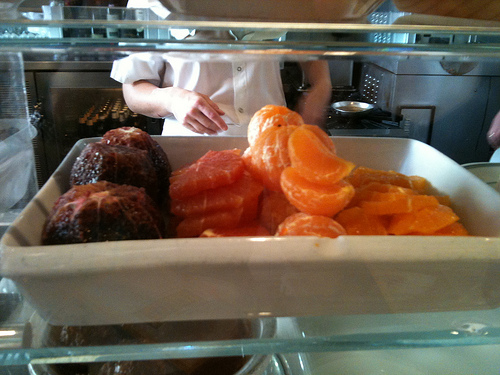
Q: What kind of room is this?
A: Kitchen.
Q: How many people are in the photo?
A: One.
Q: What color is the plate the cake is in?
A: White.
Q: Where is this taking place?
A: In a restaurant.